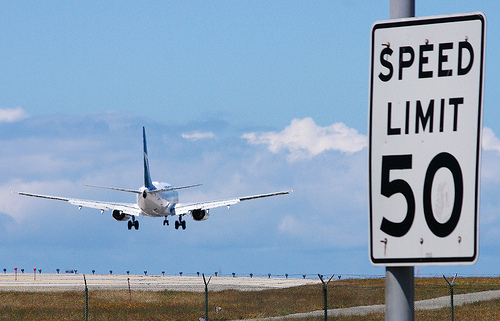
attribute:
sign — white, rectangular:
[367, 13, 485, 264]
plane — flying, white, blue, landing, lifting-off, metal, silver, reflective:
[11, 126, 293, 231]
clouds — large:
[291, 117, 364, 266]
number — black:
[379, 153, 464, 238]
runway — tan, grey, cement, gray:
[1, 275, 314, 292]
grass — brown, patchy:
[3, 291, 249, 321]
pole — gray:
[386, 266, 415, 320]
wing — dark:
[176, 191, 294, 218]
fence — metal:
[0, 273, 388, 321]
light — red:
[34, 267, 38, 281]